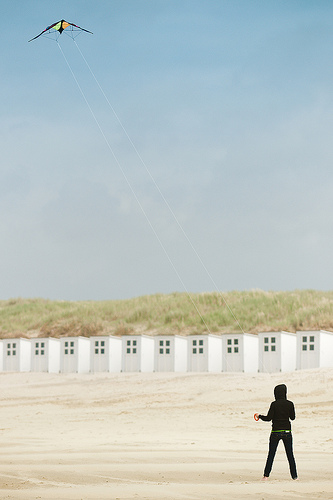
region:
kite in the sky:
[23, 10, 101, 50]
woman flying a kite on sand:
[239, 372, 313, 487]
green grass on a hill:
[3, 295, 325, 328]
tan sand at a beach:
[8, 384, 240, 476]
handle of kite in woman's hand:
[252, 412, 262, 422]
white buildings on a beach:
[0, 328, 328, 380]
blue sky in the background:
[154, 21, 319, 138]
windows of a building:
[223, 334, 242, 359]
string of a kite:
[56, 54, 125, 120]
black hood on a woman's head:
[270, 380, 291, 401]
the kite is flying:
[22, 7, 91, 75]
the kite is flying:
[25, 7, 76, 46]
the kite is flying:
[21, 16, 143, 87]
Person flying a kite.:
[20, 16, 310, 492]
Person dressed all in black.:
[242, 372, 306, 486]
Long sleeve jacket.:
[259, 378, 300, 435]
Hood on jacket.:
[263, 377, 290, 405]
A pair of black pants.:
[261, 429, 307, 488]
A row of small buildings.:
[0, 326, 323, 383]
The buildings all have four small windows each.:
[2, 323, 331, 380]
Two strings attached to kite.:
[30, 9, 302, 425]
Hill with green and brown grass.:
[7, 283, 321, 331]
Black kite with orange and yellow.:
[29, 10, 95, 49]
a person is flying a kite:
[6, 2, 300, 483]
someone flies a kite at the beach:
[24, 13, 306, 485]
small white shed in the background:
[294, 326, 332, 374]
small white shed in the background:
[254, 326, 293, 380]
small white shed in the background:
[3, 335, 32, 376]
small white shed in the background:
[58, 333, 87, 383]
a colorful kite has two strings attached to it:
[21, 13, 135, 155]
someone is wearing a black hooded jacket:
[253, 378, 301, 436]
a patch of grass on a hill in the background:
[14, 287, 328, 330]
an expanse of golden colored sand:
[0, 377, 235, 491]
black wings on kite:
[68, 16, 90, 35]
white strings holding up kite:
[50, 44, 151, 173]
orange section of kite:
[58, 9, 70, 37]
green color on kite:
[47, 16, 69, 35]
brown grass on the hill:
[229, 283, 304, 311]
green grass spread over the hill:
[110, 302, 224, 335]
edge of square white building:
[237, 328, 254, 381]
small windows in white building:
[117, 331, 141, 358]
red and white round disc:
[240, 407, 265, 435]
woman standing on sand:
[237, 363, 304, 482]